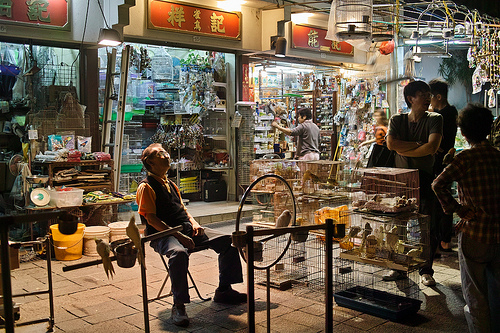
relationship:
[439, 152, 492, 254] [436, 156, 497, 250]
person in shirt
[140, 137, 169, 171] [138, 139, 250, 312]
head of person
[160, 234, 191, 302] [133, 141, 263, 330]
leg of person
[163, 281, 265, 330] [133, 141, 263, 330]
feet of person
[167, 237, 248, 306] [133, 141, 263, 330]
leg of person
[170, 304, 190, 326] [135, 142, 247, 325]
feet of man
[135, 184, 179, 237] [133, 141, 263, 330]
arm of person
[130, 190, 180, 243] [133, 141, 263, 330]
arm of person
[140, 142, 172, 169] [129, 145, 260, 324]
head of person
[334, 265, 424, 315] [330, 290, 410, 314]
cage has bottom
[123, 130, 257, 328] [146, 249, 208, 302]
man sitting stool